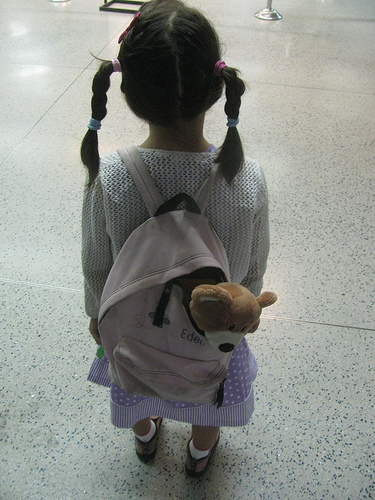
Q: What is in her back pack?
A: A teddy bear.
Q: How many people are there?
A: One.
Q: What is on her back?
A: A backpack.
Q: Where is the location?
A: An airport.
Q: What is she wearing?
A: A dress and a sweater.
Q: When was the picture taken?
A: Daytime.